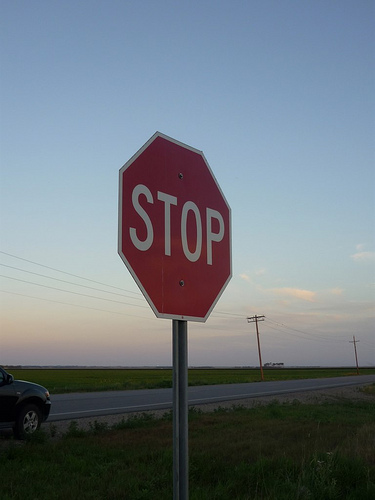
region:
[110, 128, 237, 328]
Red and white stop sign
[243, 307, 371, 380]
Telephone poles along side of roadway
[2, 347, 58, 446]
Car parked on side of roadway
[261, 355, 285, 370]
Cluster of buildings in background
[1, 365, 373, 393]
Green field near paved road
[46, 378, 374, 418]
White line painted on asphalt roadway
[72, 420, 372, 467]
Patch of dying grass surrounded by green grass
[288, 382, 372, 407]
Dirt road perpendicular to paved road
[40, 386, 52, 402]
Orange parking light on dark car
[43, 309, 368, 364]
Grey hazy clouds in sky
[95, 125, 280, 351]
this is a sign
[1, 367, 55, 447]
this is a car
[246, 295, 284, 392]
this is an electricity post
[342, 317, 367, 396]
this is an electricity post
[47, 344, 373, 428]
this is a tarmacked road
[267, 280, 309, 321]
this is a cloud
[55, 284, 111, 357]
this is a cloud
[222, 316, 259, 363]
this is a cloud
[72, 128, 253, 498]
a large stop sign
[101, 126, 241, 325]
letter written on a sign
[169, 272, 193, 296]
a small metal bolt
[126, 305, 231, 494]
a large metal post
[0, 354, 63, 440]
a car driving down the road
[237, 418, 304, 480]
grass growing on the side of the road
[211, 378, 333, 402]
a long gray road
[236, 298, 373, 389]
two rows of electric wires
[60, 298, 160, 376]
clouds during the sunset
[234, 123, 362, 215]
a clear blue sky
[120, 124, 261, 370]
red and white sign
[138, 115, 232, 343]
white letters on sign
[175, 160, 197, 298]
two screws on sign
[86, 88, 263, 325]
stop sign is octagonal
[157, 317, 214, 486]
stop sign on grey pole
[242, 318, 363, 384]
large grey telephone poles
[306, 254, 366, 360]
sky is blue and pink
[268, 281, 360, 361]
layered clouds low in sky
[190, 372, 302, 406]
road is dark grey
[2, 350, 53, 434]
vehicle parked on shoulder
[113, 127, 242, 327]
red and white stop sign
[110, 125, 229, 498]
stop sign on a pole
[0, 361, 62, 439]
front end of a car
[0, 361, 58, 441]
car puled over on the shoulder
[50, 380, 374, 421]
white line on the side of the road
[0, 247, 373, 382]
power lines running along the road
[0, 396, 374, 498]
green grass on the ground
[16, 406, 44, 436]
silver rim on the tire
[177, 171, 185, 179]
bolt on the top of the sign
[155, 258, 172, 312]
faint white line on the sign